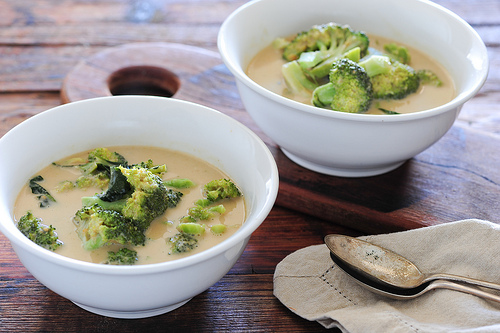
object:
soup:
[10, 145, 247, 266]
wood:
[58, 41, 499, 231]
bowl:
[215, 0, 492, 180]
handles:
[417, 271, 499, 291]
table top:
[0, 0, 500, 333]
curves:
[0, 95, 281, 277]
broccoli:
[14, 209, 65, 252]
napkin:
[271, 218, 500, 333]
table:
[0, 0, 500, 333]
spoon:
[323, 233, 500, 291]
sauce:
[10, 141, 246, 265]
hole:
[104, 63, 182, 98]